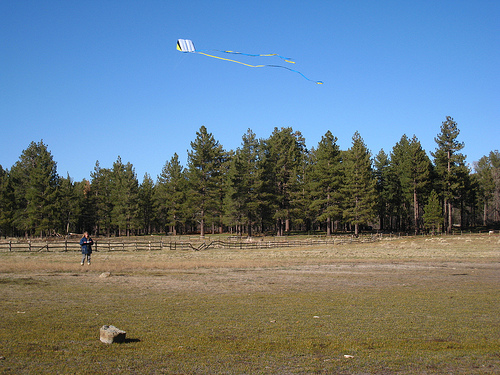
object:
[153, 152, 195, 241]
tree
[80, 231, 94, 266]
girl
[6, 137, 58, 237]
green tree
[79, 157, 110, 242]
tree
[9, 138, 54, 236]
tree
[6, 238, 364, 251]
fence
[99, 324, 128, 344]
stone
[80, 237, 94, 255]
blue coat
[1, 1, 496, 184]
sky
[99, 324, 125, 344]
tree stump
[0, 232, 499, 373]
field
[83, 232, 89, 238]
hair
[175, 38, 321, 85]
kite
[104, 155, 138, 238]
tree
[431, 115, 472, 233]
tree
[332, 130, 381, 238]
tree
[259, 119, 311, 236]
tree